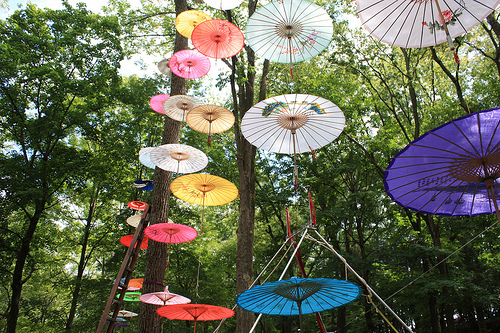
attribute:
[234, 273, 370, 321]
umbrella — blue, connected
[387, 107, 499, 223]
umbrella — purple, several, displayed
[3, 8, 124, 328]
trees — dark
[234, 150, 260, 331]
trunk — brown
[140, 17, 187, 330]
tree — green, tall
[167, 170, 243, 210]
umbrella — yellow, opened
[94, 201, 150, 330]
ladder — wooden, here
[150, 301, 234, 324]
umbrella — red, displayed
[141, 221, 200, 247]
umbrella — pink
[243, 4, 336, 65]
umbrella — white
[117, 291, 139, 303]
umbrella — green, displayed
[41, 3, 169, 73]
sky — cloudy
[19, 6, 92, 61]
leaves — green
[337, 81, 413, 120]
leaves — green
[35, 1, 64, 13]
cloud — white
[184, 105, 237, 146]
umbrella — vertical, displayed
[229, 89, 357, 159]
parasol — displayed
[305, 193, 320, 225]
string — red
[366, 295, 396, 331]
string — yellow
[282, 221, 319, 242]
sticks — framed